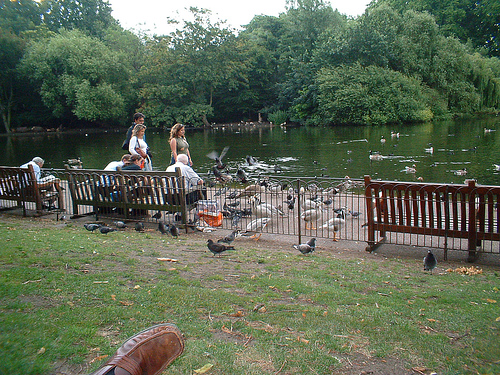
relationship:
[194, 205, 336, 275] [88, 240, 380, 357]
pigeons on ground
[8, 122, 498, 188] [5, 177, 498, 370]
lake in park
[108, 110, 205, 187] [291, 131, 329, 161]
people by pond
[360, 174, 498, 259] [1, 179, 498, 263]
bench on sidewalk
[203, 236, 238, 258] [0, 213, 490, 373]
pigeon in grass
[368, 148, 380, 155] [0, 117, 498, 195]
duck sitting on pond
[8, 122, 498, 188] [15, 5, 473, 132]
lake refelcting trees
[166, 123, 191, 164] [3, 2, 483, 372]
person walking in park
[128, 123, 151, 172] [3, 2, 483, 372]
people walking in park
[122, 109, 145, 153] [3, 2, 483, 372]
person walking in park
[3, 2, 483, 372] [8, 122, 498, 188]
park containing lake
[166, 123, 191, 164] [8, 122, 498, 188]
person walking alongside lake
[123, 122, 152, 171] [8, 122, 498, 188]
person walking alongside lake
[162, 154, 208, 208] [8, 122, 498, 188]
man walking alongside lake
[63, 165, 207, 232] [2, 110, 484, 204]
bench standing alongside pond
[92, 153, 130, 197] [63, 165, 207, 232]
person sitting on top of bench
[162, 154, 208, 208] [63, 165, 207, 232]
man sitting on top of bench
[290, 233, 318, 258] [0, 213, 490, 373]
bird standing on grass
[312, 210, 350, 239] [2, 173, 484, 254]
bird standing on sidewalk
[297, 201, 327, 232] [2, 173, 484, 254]
bird standing on sidewalk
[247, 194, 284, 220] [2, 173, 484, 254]
bird standing on sidewalk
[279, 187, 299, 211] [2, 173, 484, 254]
bird standing on sidewalk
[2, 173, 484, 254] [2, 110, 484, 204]
sidewalk built alongside pond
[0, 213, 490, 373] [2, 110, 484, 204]
grass growing next to pond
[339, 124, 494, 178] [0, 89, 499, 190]
ducks in water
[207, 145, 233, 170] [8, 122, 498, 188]
bird flying out of lake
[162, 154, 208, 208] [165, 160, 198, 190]
man wearing shirt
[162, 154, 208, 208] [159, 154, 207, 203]
man wearing shirt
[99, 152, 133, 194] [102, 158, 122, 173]
man wearing gray shirt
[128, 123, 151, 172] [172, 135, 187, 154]
people wearing shirt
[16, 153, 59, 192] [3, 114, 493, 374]
man reading in park